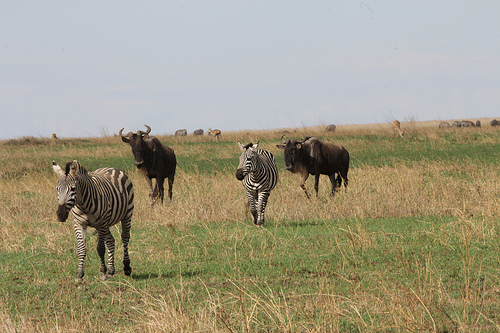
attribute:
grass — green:
[320, 274, 362, 300]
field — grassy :
[2, 136, 493, 330]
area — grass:
[2, 121, 499, 329]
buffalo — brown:
[276, 136, 356, 199]